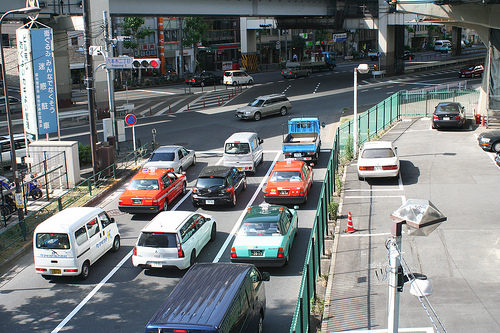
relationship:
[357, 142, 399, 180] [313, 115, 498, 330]
car on street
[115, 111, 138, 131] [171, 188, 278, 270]
sign on street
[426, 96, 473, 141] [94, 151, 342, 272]
car on street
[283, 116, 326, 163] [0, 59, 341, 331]
truck on road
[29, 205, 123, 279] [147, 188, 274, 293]
van in traffic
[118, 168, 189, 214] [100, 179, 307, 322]
red car in traffic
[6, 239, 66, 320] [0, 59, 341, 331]
tree on road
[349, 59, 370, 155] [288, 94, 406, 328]
light surrounded by fence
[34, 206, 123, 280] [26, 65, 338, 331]
van on street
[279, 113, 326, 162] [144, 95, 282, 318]
truck on road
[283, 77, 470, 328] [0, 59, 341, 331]
fence along road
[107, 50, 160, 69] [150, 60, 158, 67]
white signal with light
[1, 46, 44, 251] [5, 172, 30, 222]
pole with attached sign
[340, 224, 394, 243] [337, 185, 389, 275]
lines painted in parking lot